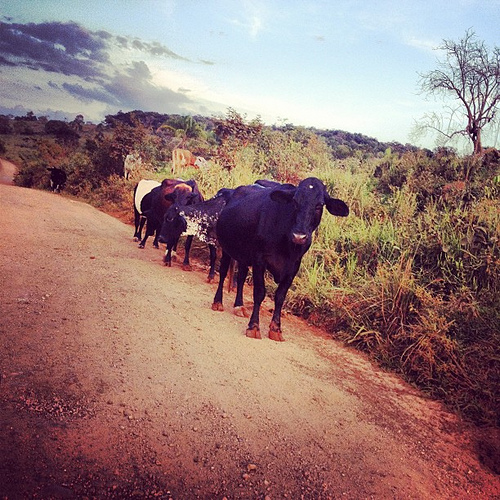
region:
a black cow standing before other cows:
[210, 175, 350, 342]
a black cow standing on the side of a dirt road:
[211, 177, 351, 342]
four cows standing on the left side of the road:
[130, 175, 350, 342]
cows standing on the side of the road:
[130, 176, 350, 341]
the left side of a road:
[0, 348, 497, 498]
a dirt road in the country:
[3, 347, 497, 496]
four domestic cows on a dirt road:
[1, 175, 498, 497]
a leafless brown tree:
[409, 23, 499, 151]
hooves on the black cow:
[209, 300, 284, 342]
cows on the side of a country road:
[131, 178, 351, 342]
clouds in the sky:
[21, 56, 174, 109]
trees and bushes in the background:
[122, 101, 393, 171]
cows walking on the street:
[41, 165, 346, 345]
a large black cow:
[220, 175, 342, 338]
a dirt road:
[15, 220, 387, 485]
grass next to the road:
[341, 222, 494, 387]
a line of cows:
[122, 165, 340, 330]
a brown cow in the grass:
[162, 135, 218, 177]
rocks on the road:
[104, 439, 328, 496]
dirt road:
[2, 155, 492, 490]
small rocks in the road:
[98, 393, 273, 494]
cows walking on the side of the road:
[122, 156, 327, 361]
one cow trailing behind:
[43, 162, 66, 195]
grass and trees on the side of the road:
[3, 95, 486, 376]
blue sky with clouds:
[3, 0, 493, 148]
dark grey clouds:
[6, 2, 221, 112]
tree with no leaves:
[411, 30, 497, 148]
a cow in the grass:
[167, 143, 220, 177]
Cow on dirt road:
[130, 171, 351, 342]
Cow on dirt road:
[127, 171, 352, 346]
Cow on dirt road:
[120, 168, 360, 348]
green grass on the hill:
[437, 218, 465, 264]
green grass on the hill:
[445, 257, 471, 287]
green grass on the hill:
[381, 218, 393, 254]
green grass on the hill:
[421, 196, 432, 231]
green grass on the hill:
[345, 248, 355, 281]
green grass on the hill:
[302, 257, 315, 297]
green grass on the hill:
[317, 220, 332, 253]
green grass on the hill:
[331, 215, 353, 250]